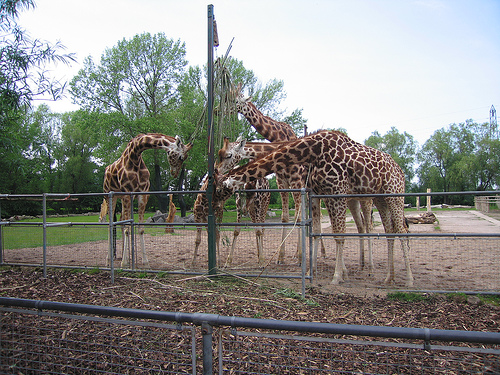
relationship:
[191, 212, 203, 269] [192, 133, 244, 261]
leg of giraffe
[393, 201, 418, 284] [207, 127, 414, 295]
leg of giraffe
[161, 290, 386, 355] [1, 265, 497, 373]
mulch on ground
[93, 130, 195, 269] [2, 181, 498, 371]
giraffe in enclosure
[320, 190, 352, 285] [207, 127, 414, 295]
leg of giraffe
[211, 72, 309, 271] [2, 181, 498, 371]
giraffe in enclosure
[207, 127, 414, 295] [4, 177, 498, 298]
giraffe in pen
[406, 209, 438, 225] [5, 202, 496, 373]
stump lying on ground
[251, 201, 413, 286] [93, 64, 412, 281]
legs of giraffe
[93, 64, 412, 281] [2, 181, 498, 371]
giraffe in enclosure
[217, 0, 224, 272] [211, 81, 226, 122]
pole holdings food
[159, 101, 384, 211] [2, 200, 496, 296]
giraffes by dirt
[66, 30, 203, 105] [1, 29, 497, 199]
leaves on trees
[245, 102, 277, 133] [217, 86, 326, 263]
neck of giraffe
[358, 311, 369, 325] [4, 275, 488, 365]
part of ground